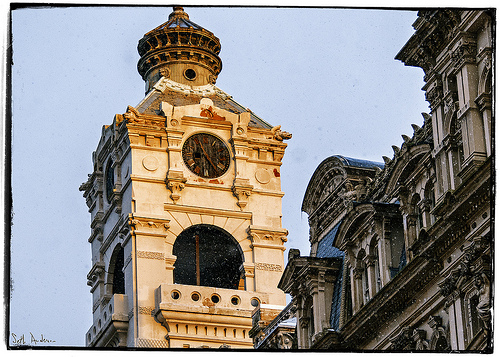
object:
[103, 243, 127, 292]
arch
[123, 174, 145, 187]
corner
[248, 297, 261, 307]
holes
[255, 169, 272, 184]
circle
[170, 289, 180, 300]
opening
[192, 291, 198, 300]
opening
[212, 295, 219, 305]
opening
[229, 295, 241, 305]
opening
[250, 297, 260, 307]
opening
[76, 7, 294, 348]
building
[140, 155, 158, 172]
circle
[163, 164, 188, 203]
carving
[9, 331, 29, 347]
seth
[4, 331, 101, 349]
name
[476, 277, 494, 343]
sculpture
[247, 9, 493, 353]
buildings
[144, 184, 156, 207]
concrete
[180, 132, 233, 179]
clock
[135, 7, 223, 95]
dome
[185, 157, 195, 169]
numbers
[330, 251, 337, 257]
tiles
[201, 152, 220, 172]
hand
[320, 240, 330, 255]
color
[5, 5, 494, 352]
photo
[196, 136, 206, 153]
hand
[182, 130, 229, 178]
face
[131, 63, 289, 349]
wall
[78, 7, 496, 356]
two castle